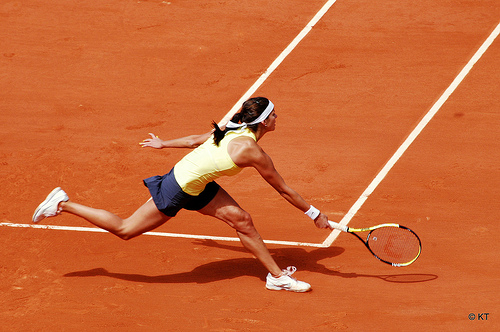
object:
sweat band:
[303, 204, 320, 220]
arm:
[246, 145, 333, 230]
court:
[0, 3, 499, 329]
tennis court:
[0, 2, 500, 324]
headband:
[225, 100, 274, 131]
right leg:
[64, 198, 182, 241]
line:
[209, 0, 336, 136]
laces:
[283, 266, 297, 275]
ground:
[316, 132, 352, 172]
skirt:
[140, 166, 222, 217]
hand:
[139, 132, 163, 148]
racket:
[327, 220, 422, 268]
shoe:
[31, 186, 69, 223]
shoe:
[264, 266, 313, 293]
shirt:
[173, 126, 258, 196]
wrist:
[306, 204, 320, 218]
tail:
[209, 113, 243, 147]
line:
[166, 232, 237, 243]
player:
[29, 96, 335, 294]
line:
[0, 218, 107, 234]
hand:
[314, 211, 334, 232]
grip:
[326, 220, 348, 233]